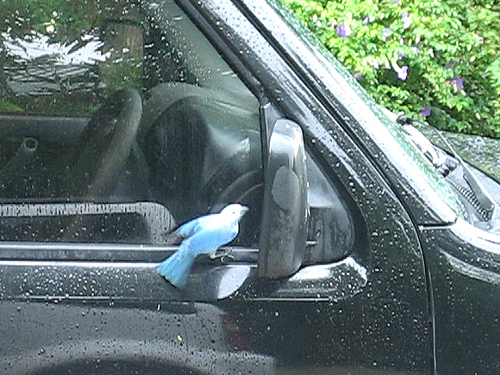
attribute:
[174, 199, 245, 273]
bird — blue, white, picture, small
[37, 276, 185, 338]
door — reflection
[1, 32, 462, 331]
car — painted, green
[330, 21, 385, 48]
flowers — purple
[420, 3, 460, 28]
bushes — background, green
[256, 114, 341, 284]
mirror — black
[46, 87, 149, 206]
steering wheel — black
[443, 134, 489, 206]
windshield wiper — here, blade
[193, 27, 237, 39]
paint — peeling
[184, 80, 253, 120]
dashboard — black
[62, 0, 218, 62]
window — reflection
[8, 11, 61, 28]
leaves — glare